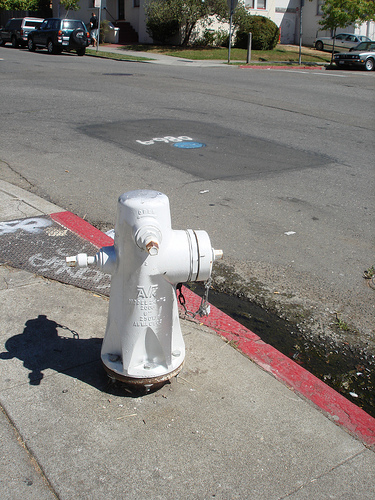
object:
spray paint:
[1, 213, 56, 240]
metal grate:
[0, 213, 112, 300]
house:
[98, 0, 299, 48]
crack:
[2, 156, 51, 198]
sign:
[221, 0, 235, 65]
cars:
[26, 14, 94, 59]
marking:
[134, 132, 197, 147]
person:
[88, 11, 100, 47]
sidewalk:
[87, 43, 336, 68]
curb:
[0, 173, 374, 448]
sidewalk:
[0, 178, 374, 498]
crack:
[1, 186, 47, 223]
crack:
[0, 276, 53, 293]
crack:
[0, 354, 101, 393]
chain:
[174, 271, 219, 324]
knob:
[62, 244, 118, 275]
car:
[332, 38, 375, 73]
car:
[312, 29, 366, 56]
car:
[0, 11, 47, 50]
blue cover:
[173, 139, 205, 150]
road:
[0, 35, 375, 419]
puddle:
[185, 271, 375, 420]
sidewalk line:
[2, 402, 62, 498]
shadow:
[0, 303, 171, 413]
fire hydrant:
[66, 188, 227, 394]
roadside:
[90, 159, 375, 432]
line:
[175, 281, 375, 448]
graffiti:
[27, 236, 112, 293]